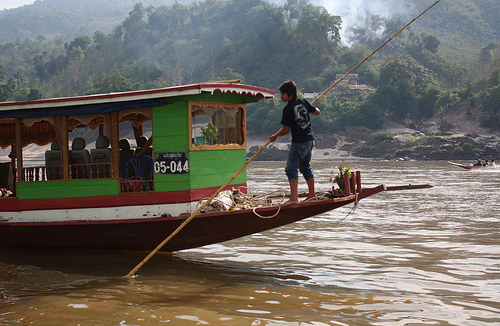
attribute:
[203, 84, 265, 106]
trim — white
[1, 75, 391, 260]
boat — small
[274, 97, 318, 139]
tee shirt — black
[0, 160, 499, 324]
water — dirty